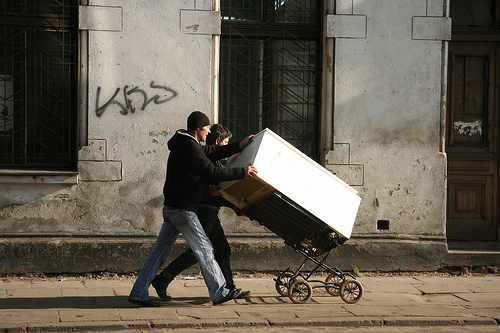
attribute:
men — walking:
[126, 105, 258, 316]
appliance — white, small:
[214, 126, 368, 264]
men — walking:
[154, 117, 251, 307]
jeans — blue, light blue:
[128, 199, 234, 310]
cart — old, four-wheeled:
[272, 233, 365, 308]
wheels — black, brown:
[339, 273, 365, 305]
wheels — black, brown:
[324, 269, 348, 298]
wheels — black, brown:
[287, 277, 316, 305]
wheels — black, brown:
[272, 268, 301, 299]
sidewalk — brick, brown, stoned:
[2, 268, 500, 328]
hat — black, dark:
[187, 111, 211, 133]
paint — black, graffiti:
[91, 79, 179, 126]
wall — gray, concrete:
[0, 4, 459, 273]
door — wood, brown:
[446, 34, 500, 245]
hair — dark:
[204, 123, 236, 149]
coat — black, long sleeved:
[159, 129, 246, 213]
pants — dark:
[160, 206, 235, 298]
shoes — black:
[209, 285, 245, 306]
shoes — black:
[128, 291, 159, 313]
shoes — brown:
[226, 283, 252, 302]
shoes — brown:
[150, 272, 173, 301]